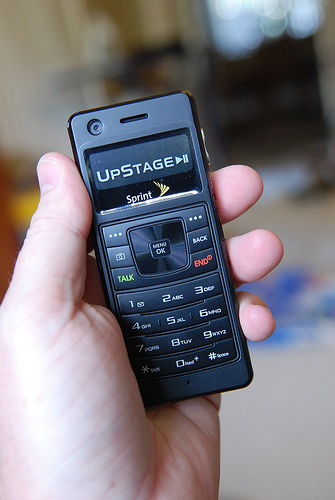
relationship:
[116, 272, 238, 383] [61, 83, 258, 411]
keypad on cellphone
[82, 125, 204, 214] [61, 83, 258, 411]
screen on cellphone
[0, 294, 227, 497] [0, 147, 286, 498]
palm on person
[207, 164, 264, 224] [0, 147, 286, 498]
middle finger on person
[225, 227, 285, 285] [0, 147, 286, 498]
finger on person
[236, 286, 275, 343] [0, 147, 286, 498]
finger on person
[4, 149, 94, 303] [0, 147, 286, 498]
finger on person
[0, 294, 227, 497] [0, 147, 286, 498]
palm belonging to person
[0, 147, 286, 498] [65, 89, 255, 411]
person holding phone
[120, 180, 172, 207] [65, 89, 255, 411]
brand shown on phone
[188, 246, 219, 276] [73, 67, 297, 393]
button attached to phone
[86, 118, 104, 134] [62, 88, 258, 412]
camera built into phone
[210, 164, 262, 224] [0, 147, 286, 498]
middle finger belonging to person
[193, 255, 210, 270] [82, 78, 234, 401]
end written on phone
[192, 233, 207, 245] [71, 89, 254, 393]
word written on phone